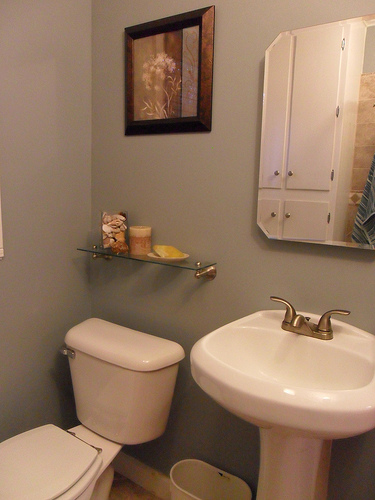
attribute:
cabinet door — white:
[258, 35, 293, 190]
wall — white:
[93, 1, 375, 500]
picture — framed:
[131, 23, 201, 122]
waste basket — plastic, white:
[168, 458, 254, 500]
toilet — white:
[0, 316, 186, 500]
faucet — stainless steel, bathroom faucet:
[268, 295, 350, 342]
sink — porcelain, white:
[189, 308, 374, 442]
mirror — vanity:
[333, 19, 373, 248]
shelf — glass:
[75, 243, 217, 281]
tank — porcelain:
[61, 317, 186, 445]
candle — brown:
[126, 225, 153, 257]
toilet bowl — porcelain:
[0, 430, 101, 500]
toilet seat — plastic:
[54, 456, 104, 500]